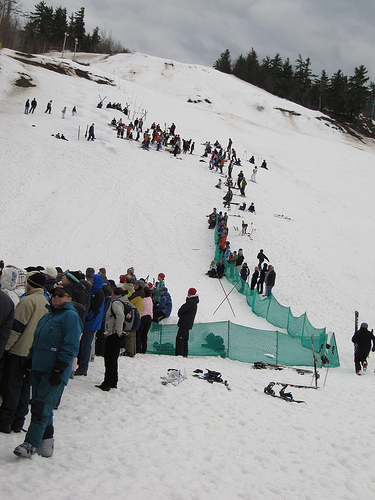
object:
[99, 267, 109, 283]
person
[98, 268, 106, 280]
head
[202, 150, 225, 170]
winter coat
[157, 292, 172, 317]
coat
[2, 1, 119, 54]
trees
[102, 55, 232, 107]
hill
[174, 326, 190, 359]
silver handle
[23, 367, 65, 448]
snow pant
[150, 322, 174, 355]
fence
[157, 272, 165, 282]
head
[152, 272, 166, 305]
person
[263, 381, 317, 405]
skis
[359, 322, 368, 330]
head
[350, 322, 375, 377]
person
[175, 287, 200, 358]
person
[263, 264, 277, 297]
person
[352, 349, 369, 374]
pants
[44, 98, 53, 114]
person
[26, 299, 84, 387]
blue coat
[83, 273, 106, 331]
blue coat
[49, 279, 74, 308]
head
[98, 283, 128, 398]
woman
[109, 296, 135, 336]
backpack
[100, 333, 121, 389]
pants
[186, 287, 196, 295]
head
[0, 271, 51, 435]
person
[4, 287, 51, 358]
coat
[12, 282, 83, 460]
person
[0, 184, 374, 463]
spectators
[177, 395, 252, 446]
snow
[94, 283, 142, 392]
person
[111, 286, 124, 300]
head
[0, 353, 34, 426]
pants